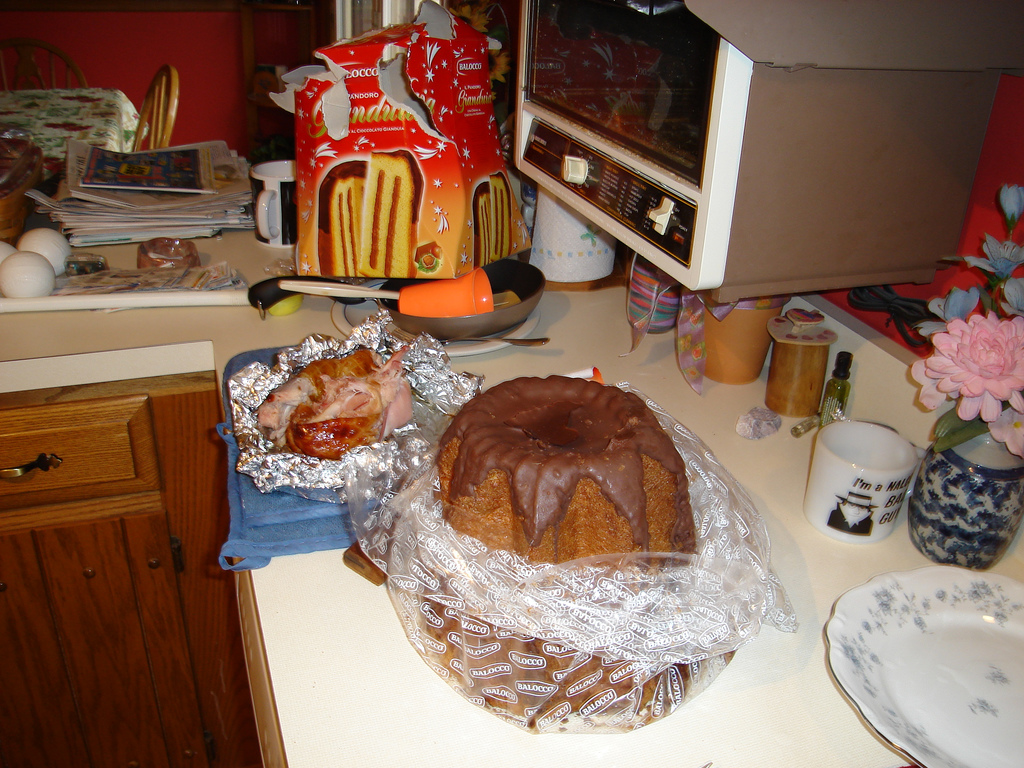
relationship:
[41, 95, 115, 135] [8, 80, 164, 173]
table cover with a tablecloth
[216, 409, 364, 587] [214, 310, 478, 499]
oven mitts beneath foil